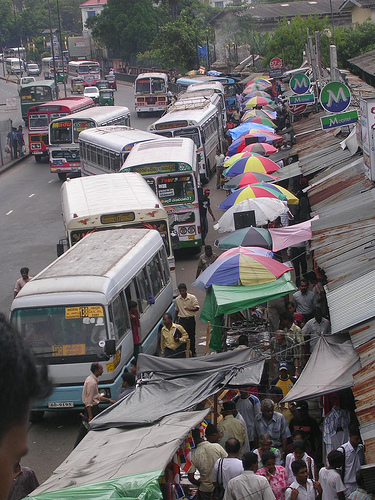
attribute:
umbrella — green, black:
[194, 254, 296, 288]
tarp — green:
[199, 282, 306, 346]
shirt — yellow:
[155, 323, 188, 355]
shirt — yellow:
[171, 293, 199, 318]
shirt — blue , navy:
[263, 392, 334, 465]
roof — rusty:
[299, 151, 373, 213]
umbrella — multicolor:
[188, 250, 293, 287]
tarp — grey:
[12, 334, 283, 499]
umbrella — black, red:
[221, 149, 282, 182]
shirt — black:
[199, 195, 210, 214]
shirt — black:
[172, 293, 198, 319]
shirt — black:
[216, 154, 226, 170]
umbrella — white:
[244, 69, 306, 169]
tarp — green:
[199, 279, 299, 352]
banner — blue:
[195, 42, 208, 58]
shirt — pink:
[258, 466, 293, 497]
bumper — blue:
[28, 383, 111, 410]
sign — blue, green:
[270, 55, 286, 80]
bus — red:
[25, 93, 89, 154]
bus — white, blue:
[7, 224, 177, 425]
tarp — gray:
[84, 345, 273, 427]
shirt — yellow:
[155, 325, 187, 351]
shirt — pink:
[255, 465, 285, 494]